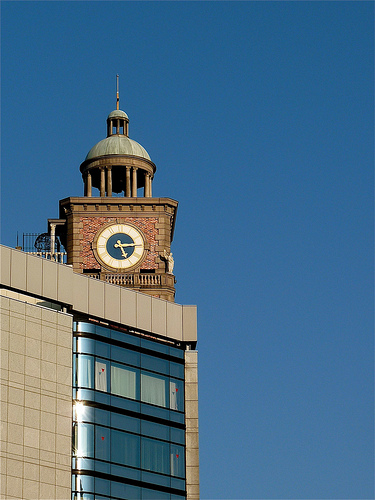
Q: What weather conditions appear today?
A: It is clear.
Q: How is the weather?
A: It is clear.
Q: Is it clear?
A: Yes, it is clear.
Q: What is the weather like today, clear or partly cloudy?
A: It is clear.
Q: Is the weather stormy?
A: No, it is clear.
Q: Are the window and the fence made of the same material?
A: No, the window is made of glass and the fence is made of metal.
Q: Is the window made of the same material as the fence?
A: No, the window is made of glass and the fence is made of metal.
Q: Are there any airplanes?
A: No, there are no airplanes.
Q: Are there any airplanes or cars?
A: No, there are no airplanes or cars.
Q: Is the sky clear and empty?
A: Yes, the sky is clear and empty.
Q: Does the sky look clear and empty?
A: Yes, the sky is clear and empty.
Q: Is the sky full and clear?
A: No, the sky is clear but empty.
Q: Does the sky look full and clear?
A: No, the sky is clear but empty.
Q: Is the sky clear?
A: Yes, the sky is clear.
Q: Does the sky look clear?
A: Yes, the sky is clear.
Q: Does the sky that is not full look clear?
A: Yes, the sky is clear.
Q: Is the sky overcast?
A: No, the sky is clear.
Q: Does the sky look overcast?
A: No, the sky is clear.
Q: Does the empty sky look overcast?
A: No, the sky is clear.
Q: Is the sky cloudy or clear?
A: The sky is clear.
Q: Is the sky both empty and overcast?
A: No, the sky is empty but clear.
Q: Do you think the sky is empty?
A: Yes, the sky is empty.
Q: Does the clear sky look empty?
A: Yes, the sky is empty.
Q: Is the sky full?
A: No, the sky is empty.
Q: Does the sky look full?
A: No, the sky is empty.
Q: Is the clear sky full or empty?
A: The sky is empty.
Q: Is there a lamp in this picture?
A: No, there are no lamps.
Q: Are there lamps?
A: No, there are no lamps.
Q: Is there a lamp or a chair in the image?
A: No, there are no lamps or chairs.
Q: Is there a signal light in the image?
A: No, there are no traffic lights.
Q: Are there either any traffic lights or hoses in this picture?
A: No, there are no traffic lights or hoses.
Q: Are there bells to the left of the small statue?
A: Yes, there is a bell to the left of the statue.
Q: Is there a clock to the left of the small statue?
A: No, there is a bell to the left of the statue.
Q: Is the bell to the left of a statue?
A: Yes, the bell is to the left of a statue.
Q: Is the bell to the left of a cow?
A: No, the bell is to the left of a statue.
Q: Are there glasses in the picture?
A: No, there are no glasses.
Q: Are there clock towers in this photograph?
A: Yes, there is a clock tower.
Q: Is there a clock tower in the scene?
A: Yes, there is a clock tower.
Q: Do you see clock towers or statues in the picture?
A: Yes, there is a clock tower.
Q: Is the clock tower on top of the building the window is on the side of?
A: Yes, the clock tower is on top of the building.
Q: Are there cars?
A: No, there are no cars.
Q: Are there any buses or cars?
A: No, there are no cars or buses.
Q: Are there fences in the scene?
A: Yes, there is a fence.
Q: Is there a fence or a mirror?
A: Yes, there is a fence.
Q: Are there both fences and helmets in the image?
A: No, there is a fence but no helmets.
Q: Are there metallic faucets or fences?
A: Yes, there is a metal fence.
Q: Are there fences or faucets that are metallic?
A: Yes, the fence is metallic.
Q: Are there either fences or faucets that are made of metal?
A: Yes, the fence is made of metal.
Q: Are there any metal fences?
A: Yes, there is a metal fence.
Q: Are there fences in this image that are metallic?
A: Yes, there is a fence that is metallic.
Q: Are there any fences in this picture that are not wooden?
A: Yes, there is a metallic fence.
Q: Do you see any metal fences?
A: Yes, there is a fence that is made of metal.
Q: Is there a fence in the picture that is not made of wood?
A: Yes, there is a fence that is made of metal.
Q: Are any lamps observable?
A: No, there are no lamps.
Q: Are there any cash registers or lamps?
A: No, there are no lamps or cash registers.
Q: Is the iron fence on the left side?
A: Yes, the fence is on the left of the image.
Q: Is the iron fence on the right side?
A: No, the fence is on the left of the image.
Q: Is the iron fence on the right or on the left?
A: The fence is on the left of the image.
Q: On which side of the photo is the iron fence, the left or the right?
A: The fence is on the left of the image.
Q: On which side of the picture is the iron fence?
A: The fence is on the left of the image.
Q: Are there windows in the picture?
A: Yes, there is a window.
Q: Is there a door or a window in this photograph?
A: Yes, there is a window.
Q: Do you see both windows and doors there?
A: No, there is a window but no doors.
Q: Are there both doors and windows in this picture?
A: No, there is a window but no doors.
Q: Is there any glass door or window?
A: Yes, there is a glass window.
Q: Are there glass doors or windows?
A: Yes, there is a glass window.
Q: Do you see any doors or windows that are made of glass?
A: Yes, the window is made of glass.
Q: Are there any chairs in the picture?
A: No, there are no chairs.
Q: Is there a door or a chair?
A: No, there are no chairs or doors.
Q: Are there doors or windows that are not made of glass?
A: No, there is a window but it is made of glass.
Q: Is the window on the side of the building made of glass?
A: Yes, the window is made of glass.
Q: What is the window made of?
A: The window is made of glass.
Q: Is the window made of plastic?
A: No, the window is made of glass.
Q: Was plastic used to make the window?
A: No, the window is made of glass.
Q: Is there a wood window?
A: No, there is a window but it is made of glass.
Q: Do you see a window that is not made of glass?
A: No, there is a window but it is made of glass.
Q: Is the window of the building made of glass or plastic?
A: The window is made of glass.